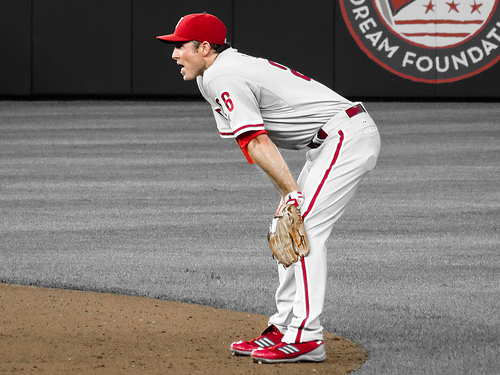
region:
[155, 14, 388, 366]
A man bent down with his hands on his knees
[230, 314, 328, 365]
A red and white pair of shoes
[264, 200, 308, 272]
A brown baseball glove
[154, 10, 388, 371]
A baseball player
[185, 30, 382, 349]
A grey, white, and red baseball uniform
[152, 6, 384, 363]
A man wearing a hat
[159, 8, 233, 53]
A red baseball hat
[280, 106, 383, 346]
A white and red pair of baseball pants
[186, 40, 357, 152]
A grey and red baseball jersey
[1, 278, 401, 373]
Brown dirt of the ground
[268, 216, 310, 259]
a baseball glove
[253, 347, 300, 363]
red shoes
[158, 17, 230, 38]
man is wearing a red hat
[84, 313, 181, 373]
dirt on the baseball field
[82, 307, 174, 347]
the dirt is brown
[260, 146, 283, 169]
the arm on the baseball player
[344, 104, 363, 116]
the man is wearing a belt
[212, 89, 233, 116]
numbers on jersey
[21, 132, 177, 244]
the baseball field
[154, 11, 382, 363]
Baseball player with his hands on his knees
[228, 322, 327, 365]
Pair of red Adidas shoes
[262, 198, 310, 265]
Worn light brown baseball mitt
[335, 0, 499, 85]
Circular red, black and white logo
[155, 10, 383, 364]
Baseball player wearing a white uniform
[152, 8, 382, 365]
Man playing baseball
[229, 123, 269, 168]
Red shirt sleeves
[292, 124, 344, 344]
Red stripe on the side of pants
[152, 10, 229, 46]
Red baseball cap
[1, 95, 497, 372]
Gray baseball field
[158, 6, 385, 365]
man has hands on knees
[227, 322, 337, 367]
man's shoes are red and white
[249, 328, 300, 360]
white stripes on man's shoes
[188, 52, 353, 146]
man's shirt is white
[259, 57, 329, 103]
red numbers on shirt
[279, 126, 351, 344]
red stripe on man's pants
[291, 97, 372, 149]
man's belt is red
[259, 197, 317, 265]
man wearing baseball mit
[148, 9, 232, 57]
man wearing a hat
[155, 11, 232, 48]
the hat is red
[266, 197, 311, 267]
base ball mitts worn by th baseball player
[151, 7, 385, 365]
Baseball player standing on the field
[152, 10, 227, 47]
red cap on the head of the player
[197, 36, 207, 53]
left ear of the player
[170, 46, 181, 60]
nose of the player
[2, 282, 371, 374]
Sandy area on the base ball field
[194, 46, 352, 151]
Baseball shirt uniform worn by the plaer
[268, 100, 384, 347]
White pants worn by the player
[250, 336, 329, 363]
left shoe worn by the player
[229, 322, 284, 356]
right shoe worn by the player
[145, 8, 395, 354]
baseball player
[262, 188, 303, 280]
brown glove worn by baseball player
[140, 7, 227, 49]
red cap worn by baseball player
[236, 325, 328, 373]
red and white shoes worn by baseball player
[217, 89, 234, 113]
red number on uniform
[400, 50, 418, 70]
A letter on a sign.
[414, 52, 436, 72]
A letter on a sign.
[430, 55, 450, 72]
A letter on a sign.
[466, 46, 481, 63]
A letter on a sign.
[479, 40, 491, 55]
A letter on a sign.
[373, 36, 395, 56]
A letter on a sign.